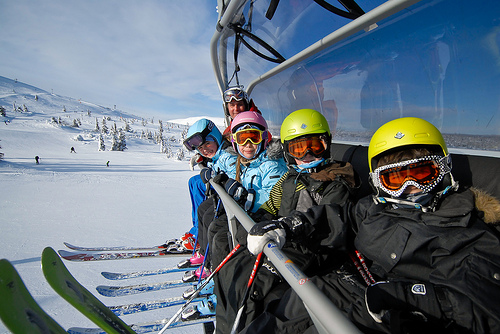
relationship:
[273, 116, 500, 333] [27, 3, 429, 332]
kid are on lift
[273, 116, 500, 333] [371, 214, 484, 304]
kid wearing jacket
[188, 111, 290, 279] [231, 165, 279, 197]
girl wears jacket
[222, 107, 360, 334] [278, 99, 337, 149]
kid wears helmet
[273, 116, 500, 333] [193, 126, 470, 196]
kid wear goggles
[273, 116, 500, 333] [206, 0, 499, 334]
kid on lift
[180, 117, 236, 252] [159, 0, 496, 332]
girl rides ski lift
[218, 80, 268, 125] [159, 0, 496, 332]
skier rides ski lift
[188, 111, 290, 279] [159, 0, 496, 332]
girl rides ski lift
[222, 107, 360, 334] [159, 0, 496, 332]
kid rides ski lift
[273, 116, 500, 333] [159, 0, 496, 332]
kid rides ski lift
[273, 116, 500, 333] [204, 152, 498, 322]
kid wear clothing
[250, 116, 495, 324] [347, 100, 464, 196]
kid wears helmet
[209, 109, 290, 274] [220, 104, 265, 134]
girl wears helmet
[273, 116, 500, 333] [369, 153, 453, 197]
kid wears glass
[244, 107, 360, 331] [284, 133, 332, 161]
kid wears glass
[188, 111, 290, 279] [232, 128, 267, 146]
girl wears glass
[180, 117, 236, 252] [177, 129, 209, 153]
girl wears goggles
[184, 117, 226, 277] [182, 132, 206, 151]
girl wears glass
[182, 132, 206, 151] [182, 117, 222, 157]
glass are on helmet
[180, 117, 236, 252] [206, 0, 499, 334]
girl riding lift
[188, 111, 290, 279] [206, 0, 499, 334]
girl riding lift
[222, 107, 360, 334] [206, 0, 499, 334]
kid riding lift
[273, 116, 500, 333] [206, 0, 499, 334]
kid riding lift